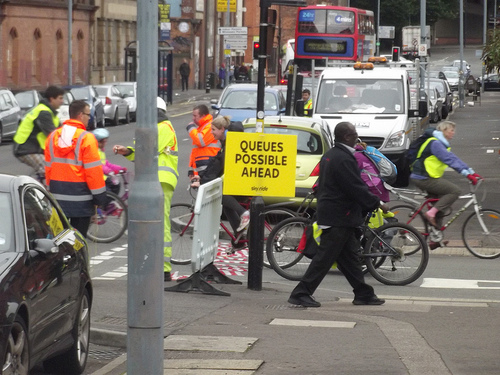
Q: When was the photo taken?
A: Daytime.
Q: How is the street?
A: Busy.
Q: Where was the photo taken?
A: At a crosswalk.